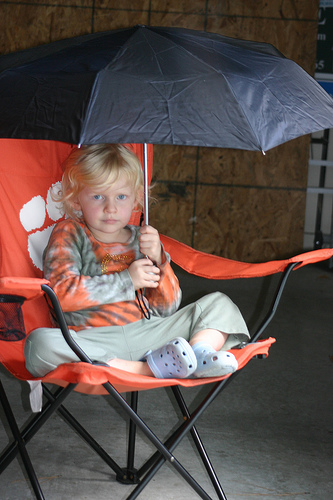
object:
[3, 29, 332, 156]
black umbrella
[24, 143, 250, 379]
child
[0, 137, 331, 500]
orange chair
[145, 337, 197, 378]
grey croc shoes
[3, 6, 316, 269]
plywood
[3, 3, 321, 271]
wall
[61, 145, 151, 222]
blonde hair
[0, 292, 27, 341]
mesh cup holder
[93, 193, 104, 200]
blue eyes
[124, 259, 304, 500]
black metal legs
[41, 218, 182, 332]
orange/grey shirt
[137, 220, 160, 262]
child's hand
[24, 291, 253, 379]
toddler pants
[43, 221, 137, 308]
sleeve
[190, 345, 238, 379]
white shoe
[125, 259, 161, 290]
small hand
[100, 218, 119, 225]
mouth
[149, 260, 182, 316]
arm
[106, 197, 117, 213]
nose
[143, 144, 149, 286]
metal post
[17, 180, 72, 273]
paw print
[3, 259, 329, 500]
cement floor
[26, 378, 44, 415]
tag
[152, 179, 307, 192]
blue line